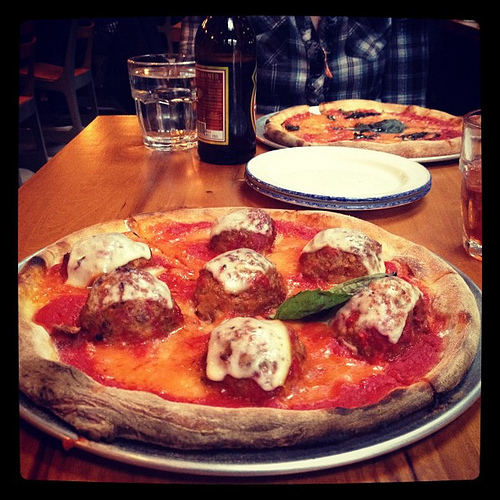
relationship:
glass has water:
[136, 43, 187, 152] [147, 86, 198, 135]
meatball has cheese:
[208, 327, 310, 403] [225, 327, 268, 370]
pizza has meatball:
[64, 212, 462, 430] [208, 327, 310, 403]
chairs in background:
[26, 41, 110, 126] [24, 26, 416, 121]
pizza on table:
[64, 212, 462, 430] [82, 121, 282, 223]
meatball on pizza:
[208, 327, 310, 403] [64, 212, 462, 430]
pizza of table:
[64, 212, 462, 430] [82, 121, 282, 223]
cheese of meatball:
[225, 327, 268, 370] [208, 327, 310, 403]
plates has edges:
[233, 136, 436, 213] [271, 185, 329, 206]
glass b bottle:
[136, 43, 187, 152] [200, 22, 258, 163]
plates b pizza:
[233, 136, 436, 213] [64, 212, 462, 430]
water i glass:
[147, 86, 198, 135] [136, 43, 187, 152]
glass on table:
[136, 43, 187, 152] [82, 121, 282, 223]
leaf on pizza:
[282, 293, 331, 322] [64, 212, 462, 430]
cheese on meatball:
[225, 327, 268, 370] [208, 327, 310, 403]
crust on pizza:
[51, 382, 281, 452] [64, 212, 462, 430]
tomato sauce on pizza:
[336, 342, 452, 407] [64, 212, 462, 430]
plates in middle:
[233, 136, 436, 213] [82, 146, 228, 181]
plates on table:
[233, 136, 436, 213] [82, 121, 282, 223]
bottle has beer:
[200, 22, 258, 163] [204, 57, 244, 144]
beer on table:
[204, 57, 244, 144] [82, 121, 282, 223]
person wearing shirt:
[230, 19, 484, 105] [194, 28, 443, 88]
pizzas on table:
[95, 77, 456, 387] [82, 121, 282, 223]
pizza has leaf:
[64, 212, 462, 430] [282, 293, 331, 322]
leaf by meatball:
[269, 270, 391, 327] [208, 327, 310, 403]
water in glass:
[147, 86, 198, 135] [136, 43, 187, 152]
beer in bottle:
[204, 57, 244, 144] [190, 0, 268, 172]